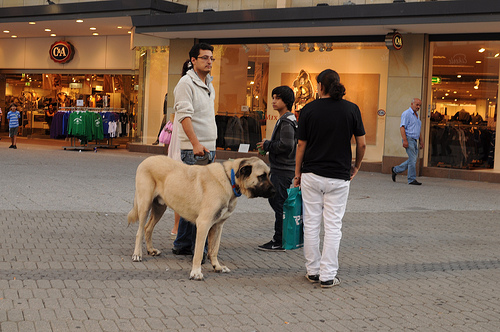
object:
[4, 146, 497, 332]
mall area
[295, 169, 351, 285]
pants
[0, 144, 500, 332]
sidewalk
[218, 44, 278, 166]
window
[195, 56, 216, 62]
glasses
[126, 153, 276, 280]
dog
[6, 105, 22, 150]
man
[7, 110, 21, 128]
shirt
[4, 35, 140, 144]
store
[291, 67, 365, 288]
woman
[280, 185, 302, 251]
bag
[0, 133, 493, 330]
floor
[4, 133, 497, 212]
concrete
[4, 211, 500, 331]
cobblestone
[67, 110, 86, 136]
merchandise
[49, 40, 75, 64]
sign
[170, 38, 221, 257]
man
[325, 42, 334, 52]
lights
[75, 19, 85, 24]
lights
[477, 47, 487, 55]
lights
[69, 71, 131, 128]
window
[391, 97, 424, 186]
man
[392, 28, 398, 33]
fixtures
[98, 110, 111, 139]
shirts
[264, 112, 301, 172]
jacket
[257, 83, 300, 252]
kid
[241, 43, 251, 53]
spotlight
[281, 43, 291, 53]
spotlight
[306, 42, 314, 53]
spotlight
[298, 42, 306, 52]
spotlight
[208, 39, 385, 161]
store window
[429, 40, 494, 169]
store window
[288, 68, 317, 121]
display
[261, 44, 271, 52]
spotlights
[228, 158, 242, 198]
blue collar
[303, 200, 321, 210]
wrinkle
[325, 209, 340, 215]
wrinkle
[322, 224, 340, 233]
wrinkle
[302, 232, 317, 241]
wrinkle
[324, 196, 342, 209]
wrinkle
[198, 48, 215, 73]
face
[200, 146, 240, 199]
leash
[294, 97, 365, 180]
shirt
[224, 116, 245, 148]
rack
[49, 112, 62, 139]
rack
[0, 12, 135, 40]
ceiling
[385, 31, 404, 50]
sign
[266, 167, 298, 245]
pants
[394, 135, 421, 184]
pants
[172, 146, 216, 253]
pants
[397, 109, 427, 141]
shirt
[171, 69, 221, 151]
shirt